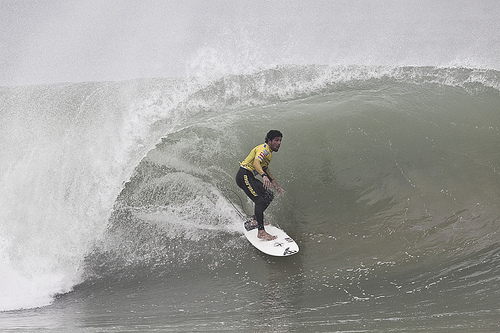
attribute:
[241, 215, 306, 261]
surfboard — white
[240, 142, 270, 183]
shirt — yellow, tight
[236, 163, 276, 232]
pants — tight, black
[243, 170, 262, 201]
lettering — yellow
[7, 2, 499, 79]
sky — hazy, grey, overcast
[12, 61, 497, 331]
water — grey, white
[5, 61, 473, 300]
ocean wave — large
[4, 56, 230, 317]
foam — white 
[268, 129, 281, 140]
hair — short , black , curly 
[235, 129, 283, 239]
surfer — barefoot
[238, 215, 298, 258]
surfboard — white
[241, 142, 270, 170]
shirt — yellow 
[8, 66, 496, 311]
wave — big , large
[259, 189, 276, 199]
knee — bend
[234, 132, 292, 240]
man — surfing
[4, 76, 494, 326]
ocean — opaque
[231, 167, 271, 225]
pants — black 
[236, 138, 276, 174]
shirt — yellow 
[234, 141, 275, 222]
rashguard — black , yellow 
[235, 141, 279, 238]
rashguard — yellow , black 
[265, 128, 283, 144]
hair — dark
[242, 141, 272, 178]
top — yellow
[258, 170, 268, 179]
watch — black